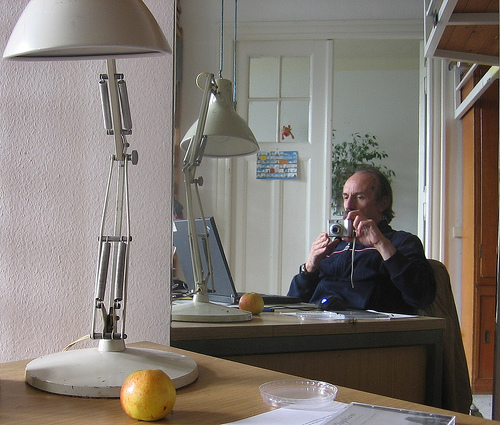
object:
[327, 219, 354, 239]
camera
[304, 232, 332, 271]
hand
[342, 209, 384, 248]
hand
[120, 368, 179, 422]
grapefruit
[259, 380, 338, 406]
bowl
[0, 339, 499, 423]
table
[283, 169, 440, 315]
man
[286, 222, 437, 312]
pull over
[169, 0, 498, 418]
mirror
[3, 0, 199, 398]
lamp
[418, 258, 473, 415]
jacket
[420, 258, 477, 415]
chair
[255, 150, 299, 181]
sign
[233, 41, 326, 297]
door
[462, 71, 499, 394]
cabinet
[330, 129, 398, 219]
houseplant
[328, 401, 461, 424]
cd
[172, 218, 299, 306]
lap top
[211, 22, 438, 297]
door way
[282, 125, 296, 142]
decal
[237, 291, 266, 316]
apple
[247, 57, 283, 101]
panes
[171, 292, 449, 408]
desk